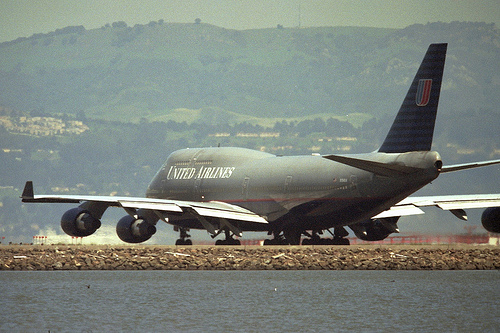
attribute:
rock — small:
[2, 245, 499, 270]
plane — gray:
[21, 43, 498, 246]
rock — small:
[2, 253, 34, 270]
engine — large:
[51, 212, 99, 244]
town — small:
[0, 115, 87, 137]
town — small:
[205, 130, 357, 152]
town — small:
[51, 182, 130, 197]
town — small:
[444, 140, 499, 155]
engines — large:
[59, 204, 103, 235]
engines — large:
[112, 214, 156, 244]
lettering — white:
[198, 162, 235, 177]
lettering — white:
[166, 164, 197, 180]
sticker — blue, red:
[413, 80, 430, 106]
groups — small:
[441, 243, 498, 268]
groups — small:
[403, 249, 456, 270]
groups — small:
[80, 247, 129, 267]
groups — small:
[171, 250, 254, 271]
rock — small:
[321, 226, 436, 283]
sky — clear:
[1, 0, 498, 243]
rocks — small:
[183, 246, 296, 268]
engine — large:
[417, 214, 497, 238]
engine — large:
[116, 213, 159, 243]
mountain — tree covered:
[7, 19, 498, 248]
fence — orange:
[344, 229, 490, 248]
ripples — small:
[64, 289, 190, 333]